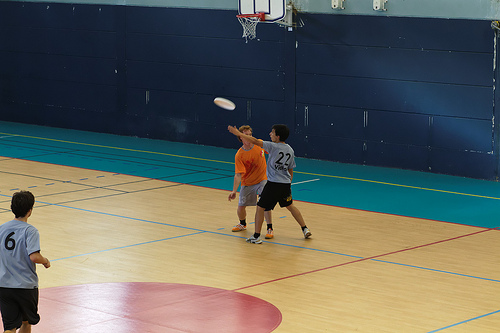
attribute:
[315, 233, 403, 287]
line — red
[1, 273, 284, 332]
circle — large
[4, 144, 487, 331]
floor — wooden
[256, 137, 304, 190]
shirt — blue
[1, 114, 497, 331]
court — green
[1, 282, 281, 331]
circle — red, large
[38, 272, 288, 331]
spot — red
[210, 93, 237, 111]
frisbee — white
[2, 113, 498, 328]
floor — wooden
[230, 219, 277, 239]
sneakers — orange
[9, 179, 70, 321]
boy — watches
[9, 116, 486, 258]
floor — blue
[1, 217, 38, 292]
shirt — blue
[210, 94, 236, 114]
frisbee — airborne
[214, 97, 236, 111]
frisbee — blue, light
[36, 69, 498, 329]
court — red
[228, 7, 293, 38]
hoop — basketball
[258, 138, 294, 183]
shirt — boy's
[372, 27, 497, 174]
wall — blue